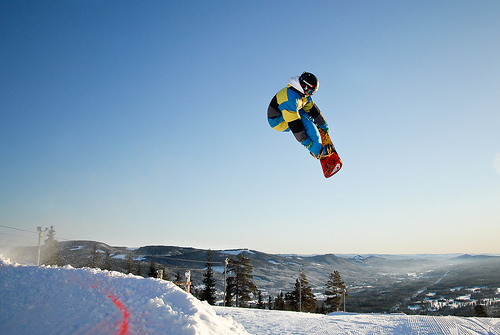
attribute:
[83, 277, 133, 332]
paint — orange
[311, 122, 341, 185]
snowboard — red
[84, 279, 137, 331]
line — orange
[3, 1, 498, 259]
sky — clear, blue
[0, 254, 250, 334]
snow drift — snowy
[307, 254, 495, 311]
hillside — distant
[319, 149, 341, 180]
snowboard — red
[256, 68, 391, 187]
pants — blue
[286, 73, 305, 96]
hood — white